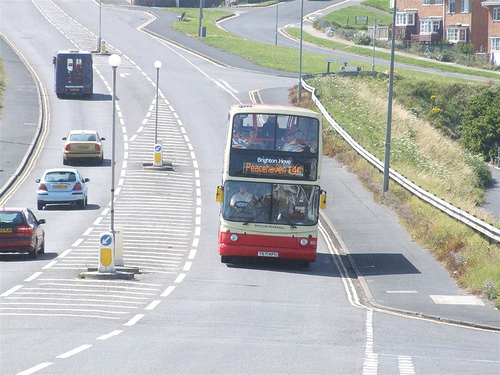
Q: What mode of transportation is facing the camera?
A: Bus.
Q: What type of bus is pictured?
A: A double decker bus.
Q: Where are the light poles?
A: In the center of the road.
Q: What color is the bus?
A: Red and white.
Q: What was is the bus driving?
A: Away from the cars.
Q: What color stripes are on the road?
A: White.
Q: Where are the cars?
A: To the left of the bus.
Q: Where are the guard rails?
A: Along the side of the road.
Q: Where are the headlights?
A: On the front of the bus.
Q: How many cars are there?
A: Three.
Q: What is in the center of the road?
A: Street lights.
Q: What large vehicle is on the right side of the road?
A: Bus.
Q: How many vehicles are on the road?
A: Five.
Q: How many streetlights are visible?
A: 2.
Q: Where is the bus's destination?
A: Peacehaven.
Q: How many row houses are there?
A: 4.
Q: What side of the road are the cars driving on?
A: Left.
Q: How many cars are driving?
A: 3.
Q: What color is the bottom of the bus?
A: Red.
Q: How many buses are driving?
A: 2.